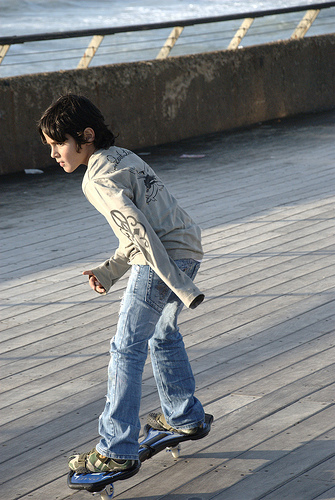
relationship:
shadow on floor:
[126, 436, 333, 497] [3, 110, 335, 498]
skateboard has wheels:
[66, 413, 217, 499] [92, 485, 117, 499]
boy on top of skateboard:
[34, 93, 208, 473] [66, 413, 217, 499]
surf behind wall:
[0, 4, 334, 79] [0, 33, 334, 175]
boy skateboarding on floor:
[34, 93, 208, 473] [3, 110, 335, 498]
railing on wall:
[0, 1, 334, 76] [0, 33, 334, 175]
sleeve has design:
[76, 177, 206, 310] [108, 210, 159, 272]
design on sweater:
[108, 210, 159, 272] [82, 146, 207, 310]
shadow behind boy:
[126, 436, 333, 497] [34, 93, 208, 473]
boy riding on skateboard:
[34, 93, 208, 473] [66, 413, 217, 499]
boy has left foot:
[34, 93, 208, 473] [67, 452, 140, 479]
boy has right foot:
[34, 93, 208, 473] [145, 410, 209, 438]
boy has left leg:
[34, 93, 208, 473] [95, 264, 171, 456]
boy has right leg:
[34, 93, 208, 473] [151, 257, 209, 418]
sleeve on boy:
[76, 177, 206, 310] [34, 93, 208, 473]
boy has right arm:
[34, 93, 208, 473] [85, 232, 130, 295]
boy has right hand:
[34, 93, 208, 473] [81, 268, 113, 295]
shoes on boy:
[66, 445, 138, 475] [34, 93, 208, 473]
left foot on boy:
[67, 452, 140, 479] [34, 93, 208, 473]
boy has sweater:
[34, 93, 208, 473] [82, 146, 207, 310]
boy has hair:
[34, 93, 208, 473] [38, 92, 113, 150]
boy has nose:
[34, 93, 208, 473] [51, 150, 61, 159]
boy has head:
[34, 93, 208, 473] [36, 95, 118, 174]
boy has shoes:
[34, 93, 208, 473] [66, 445, 138, 475]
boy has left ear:
[34, 93, 208, 473] [82, 125, 94, 142]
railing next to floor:
[0, 1, 334, 76] [3, 110, 335, 498]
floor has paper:
[3, 110, 335, 498] [23, 164, 44, 176]